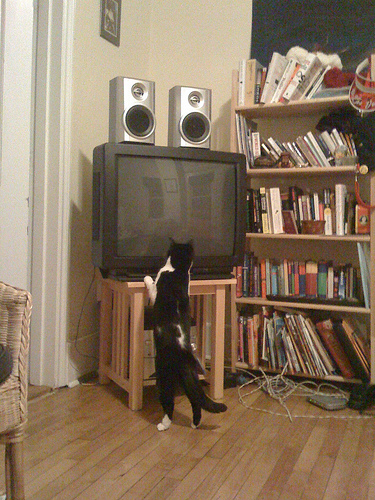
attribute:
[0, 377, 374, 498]
floor — wood, hardwood, wooden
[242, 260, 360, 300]
book — small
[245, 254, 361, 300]
books — small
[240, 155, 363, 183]
shelf — full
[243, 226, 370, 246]
shelf — full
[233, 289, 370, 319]
shelf — full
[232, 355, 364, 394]
shelf — full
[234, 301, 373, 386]
shelf — full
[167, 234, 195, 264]
head — black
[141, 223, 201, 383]
cat — black, white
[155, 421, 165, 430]
paw — white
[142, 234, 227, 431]
cat — black, white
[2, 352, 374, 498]
floor — brown